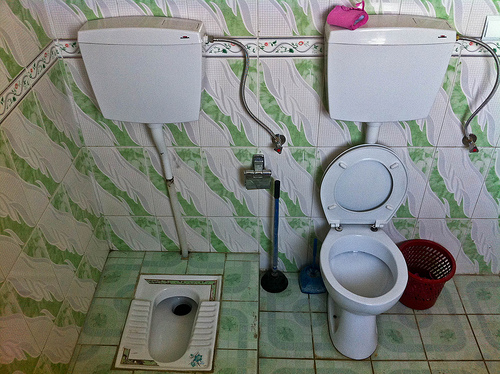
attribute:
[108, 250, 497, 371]
tile — green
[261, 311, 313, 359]
tiles — green, desiged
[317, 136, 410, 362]
toilet — porcelain, white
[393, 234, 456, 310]
basket — red, holey, on the right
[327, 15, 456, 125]
tank — mounted, white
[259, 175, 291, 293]
plunger — black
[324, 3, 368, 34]
item — pink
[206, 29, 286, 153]
pipe — silver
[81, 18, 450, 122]
bathroom fixtures — side by side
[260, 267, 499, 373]
floor — gree, green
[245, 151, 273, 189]
object — silver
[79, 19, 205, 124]
water tak — white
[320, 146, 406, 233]
toilet seat — plastic